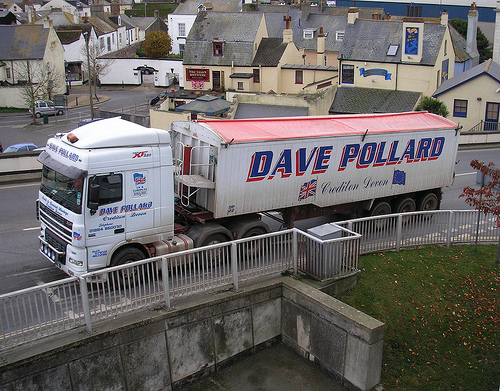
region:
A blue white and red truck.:
[34, 111, 463, 290]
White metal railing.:
[1, 205, 498, 352]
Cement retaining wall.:
[0, 273, 384, 390]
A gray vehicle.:
[28, 97, 67, 120]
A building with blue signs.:
[338, 6, 458, 98]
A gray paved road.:
[0, 139, 499, 338]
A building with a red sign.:
[183, 10, 272, 91]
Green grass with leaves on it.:
[331, 240, 498, 389]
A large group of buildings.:
[0, 0, 499, 130]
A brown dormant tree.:
[81, 33, 111, 93]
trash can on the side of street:
[303, 222, 347, 279]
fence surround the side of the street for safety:
[2, 208, 498, 348]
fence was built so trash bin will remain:
[287, 214, 363, 281]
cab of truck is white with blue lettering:
[36, 114, 178, 283]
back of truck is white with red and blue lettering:
[173, 110, 453, 218]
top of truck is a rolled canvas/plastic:
[171, 108, 458, 140]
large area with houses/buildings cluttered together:
[1, 0, 498, 132]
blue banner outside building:
[335, 19, 454, 94]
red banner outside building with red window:
[183, 39, 226, 90]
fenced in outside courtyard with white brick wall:
[94, 37, 184, 86]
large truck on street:
[22, 100, 467, 289]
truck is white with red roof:
[167, 98, 463, 213]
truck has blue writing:
[238, 134, 454, 188]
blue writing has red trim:
[238, 136, 450, 181]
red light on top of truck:
[53, 123, 85, 153]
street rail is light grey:
[36, 234, 281, 309]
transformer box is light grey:
[297, 215, 357, 285]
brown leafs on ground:
[402, 256, 497, 367]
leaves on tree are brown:
[457, 145, 498, 232]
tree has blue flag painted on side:
[382, 166, 413, 193]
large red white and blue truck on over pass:
[33, 108, 465, 281]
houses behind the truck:
[1, 0, 497, 129]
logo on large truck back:
[241, 134, 448, 199]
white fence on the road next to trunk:
[1, 211, 498, 351]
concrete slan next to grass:
[277, 276, 385, 389]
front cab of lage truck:
[36, 114, 178, 284]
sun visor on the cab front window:
[37, 150, 88, 180]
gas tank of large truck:
[147, 231, 197, 266]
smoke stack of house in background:
[316, 26, 326, 68]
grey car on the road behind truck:
[28, 101, 65, 117]